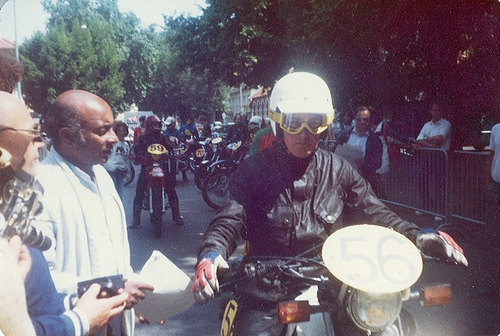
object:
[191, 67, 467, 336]
biker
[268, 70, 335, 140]
helmet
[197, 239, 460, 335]
motorcycle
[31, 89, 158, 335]
man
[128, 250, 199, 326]
paper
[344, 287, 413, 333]
light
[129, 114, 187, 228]
person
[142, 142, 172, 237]
bike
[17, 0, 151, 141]
tree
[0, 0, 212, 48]
sky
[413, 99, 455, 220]
man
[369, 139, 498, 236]
fence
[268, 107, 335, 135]
goggles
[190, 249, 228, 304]
glove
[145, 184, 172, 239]
wheel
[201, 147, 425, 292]
jacket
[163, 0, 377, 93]
tree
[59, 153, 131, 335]
shirt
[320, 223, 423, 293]
circle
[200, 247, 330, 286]
handlebars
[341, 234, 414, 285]
56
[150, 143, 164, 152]
59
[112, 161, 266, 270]
shade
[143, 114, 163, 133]
helmet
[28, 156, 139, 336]
jacket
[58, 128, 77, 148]
ear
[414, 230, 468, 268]
glove